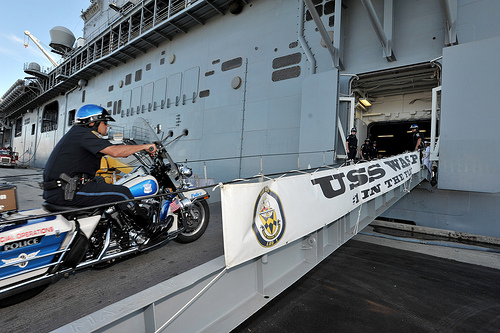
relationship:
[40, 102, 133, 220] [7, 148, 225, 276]
officer on motorcycle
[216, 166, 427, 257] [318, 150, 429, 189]
banner says uss wasp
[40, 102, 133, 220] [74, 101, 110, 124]
officer wears helmet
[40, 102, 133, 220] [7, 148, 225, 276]
officer rides motorcycle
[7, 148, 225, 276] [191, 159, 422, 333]
motorcycle goes up ramp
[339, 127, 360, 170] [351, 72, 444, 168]
officer standing at door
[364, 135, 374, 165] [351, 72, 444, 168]
officer standing at door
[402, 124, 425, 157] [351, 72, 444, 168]
officer standing at door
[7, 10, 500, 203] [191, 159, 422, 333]
boat has ramp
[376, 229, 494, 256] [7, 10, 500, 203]
water next to boat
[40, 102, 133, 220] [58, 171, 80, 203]
officer wears gun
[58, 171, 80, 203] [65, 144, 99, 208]
gun on side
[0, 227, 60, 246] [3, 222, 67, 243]
letters spell special operations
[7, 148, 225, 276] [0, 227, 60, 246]
motorcycle has letters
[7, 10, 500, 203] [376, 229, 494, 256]
boat in water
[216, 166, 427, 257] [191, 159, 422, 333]
banner on ramp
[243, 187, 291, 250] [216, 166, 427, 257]
emblem on banner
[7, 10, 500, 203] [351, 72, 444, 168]
boat has entryway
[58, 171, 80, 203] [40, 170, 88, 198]
gun on holster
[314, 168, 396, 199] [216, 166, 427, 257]
letters on banner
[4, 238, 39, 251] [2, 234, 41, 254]
letters on sign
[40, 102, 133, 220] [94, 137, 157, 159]
policeman has arm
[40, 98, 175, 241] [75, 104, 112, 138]
officer has head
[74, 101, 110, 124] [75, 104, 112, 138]
helmet on head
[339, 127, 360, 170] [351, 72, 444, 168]
policeman stands in doorway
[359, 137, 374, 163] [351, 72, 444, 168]
officer stands in doorway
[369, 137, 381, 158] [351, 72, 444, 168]
people stands in doorway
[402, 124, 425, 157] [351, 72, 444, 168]
policeman stands in doorway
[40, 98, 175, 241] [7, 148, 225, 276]
officer on motorcycle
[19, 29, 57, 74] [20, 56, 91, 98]
crane on top of building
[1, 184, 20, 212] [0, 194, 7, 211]
box has stickers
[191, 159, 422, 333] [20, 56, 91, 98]
ramp leads to building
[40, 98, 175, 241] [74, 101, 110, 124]
officer wears helmet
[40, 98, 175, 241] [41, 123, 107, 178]
officer wears shirt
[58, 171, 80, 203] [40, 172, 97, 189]
gun on belt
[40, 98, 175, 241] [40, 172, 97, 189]
officer has belt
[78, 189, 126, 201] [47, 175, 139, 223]
stripe on pants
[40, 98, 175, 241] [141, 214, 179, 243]
officer wears boot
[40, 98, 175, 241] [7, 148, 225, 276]
officer sits on bike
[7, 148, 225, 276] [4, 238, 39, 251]
bike says police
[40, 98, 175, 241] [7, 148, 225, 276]
officer rides bike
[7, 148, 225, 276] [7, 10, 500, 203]
bike goes on to boat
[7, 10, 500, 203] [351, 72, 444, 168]
ship has doorway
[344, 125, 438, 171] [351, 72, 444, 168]
people in doorway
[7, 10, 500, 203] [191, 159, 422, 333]
ship has gangplank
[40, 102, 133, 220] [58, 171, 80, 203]
officer has handgun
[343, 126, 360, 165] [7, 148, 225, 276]
officer waits for motorcycle